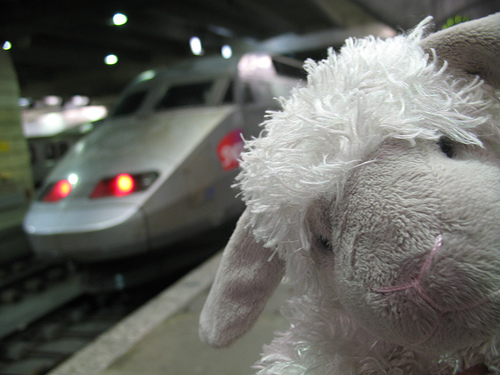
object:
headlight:
[116, 173, 134, 193]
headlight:
[57, 180, 72, 197]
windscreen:
[156, 81, 211, 109]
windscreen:
[113, 88, 151, 116]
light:
[2, 41, 12, 50]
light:
[105, 55, 118, 64]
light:
[190, 37, 201, 55]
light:
[222, 45, 232, 59]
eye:
[320, 236, 332, 249]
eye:
[440, 138, 454, 157]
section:
[230, 267, 264, 290]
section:
[320, 314, 348, 351]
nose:
[375, 235, 440, 291]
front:
[25, 203, 149, 263]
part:
[171, 87, 195, 102]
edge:
[139, 109, 234, 206]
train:
[22, 52, 318, 260]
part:
[39, 325, 87, 344]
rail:
[0, 261, 198, 374]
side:
[242, 68, 273, 130]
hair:
[235, 27, 479, 252]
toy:
[202, 11, 499, 375]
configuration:
[368, 234, 443, 310]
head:
[196, 11, 499, 353]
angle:
[198, 11, 500, 374]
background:
[0, 0, 499, 375]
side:
[148, 106, 244, 243]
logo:
[217, 130, 245, 171]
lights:
[113, 13, 128, 26]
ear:
[198, 210, 289, 348]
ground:
[0, 241, 270, 372]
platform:
[46, 247, 299, 375]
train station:
[2, 0, 499, 375]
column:
[0, 29, 37, 225]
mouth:
[408, 288, 497, 348]